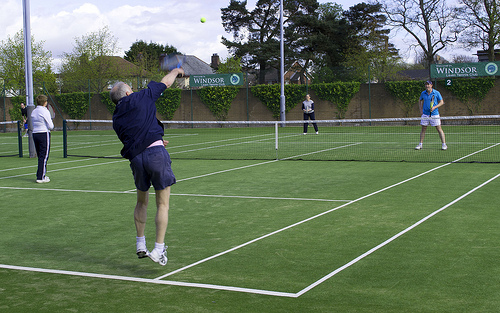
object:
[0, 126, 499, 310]
court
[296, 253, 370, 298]
lines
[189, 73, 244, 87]
sign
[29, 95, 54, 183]
person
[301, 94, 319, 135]
person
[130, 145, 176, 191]
short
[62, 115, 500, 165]
net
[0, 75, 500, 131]
wall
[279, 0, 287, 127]
lights poles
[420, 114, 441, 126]
shorts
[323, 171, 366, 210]
ground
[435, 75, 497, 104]
grass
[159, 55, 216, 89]
house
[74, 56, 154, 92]
house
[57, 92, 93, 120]
grass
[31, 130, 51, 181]
pants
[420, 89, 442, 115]
shirt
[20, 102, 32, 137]
person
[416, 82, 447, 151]
man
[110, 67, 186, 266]
man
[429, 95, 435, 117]
racket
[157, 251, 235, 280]
lines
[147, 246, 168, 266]
shoes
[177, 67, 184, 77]
hand